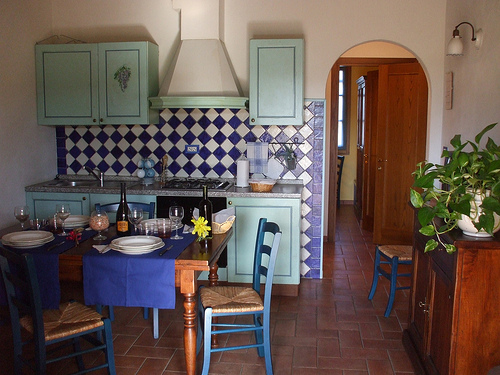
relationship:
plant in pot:
[410, 119, 499, 254] [452, 186, 499, 238]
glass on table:
[156, 217, 173, 238] [1, 213, 239, 374]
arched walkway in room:
[320, 38, 432, 280] [334, 77, 414, 229]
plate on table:
[112, 237, 161, 247] [34, 215, 233, 267]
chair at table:
[193, 214, 288, 374] [80, 220, 235, 367]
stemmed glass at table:
[115, 175, 132, 239] [18, 207, 226, 371]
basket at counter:
[246, 174, 283, 195] [34, 163, 319, 309]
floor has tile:
[279, 294, 406, 373] [317, 337, 340, 359]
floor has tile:
[279, 294, 406, 373] [361, 320, 381, 340]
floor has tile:
[279, 294, 406, 373] [317, 317, 359, 329]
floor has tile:
[279, 294, 406, 373] [296, 317, 315, 328]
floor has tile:
[279, 294, 406, 373] [316, 356, 366, 371]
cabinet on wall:
[249, 36, 309, 122] [29, 67, 335, 307]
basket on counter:
[220, 168, 287, 200] [44, 159, 304, 221]